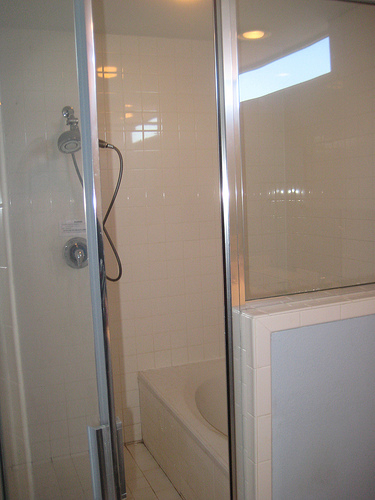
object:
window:
[236, 36, 332, 106]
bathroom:
[0, 0, 375, 500]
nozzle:
[61, 140, 79, 152]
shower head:
[57, 130, 114, 154]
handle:
[87, 416, 127, 500]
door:
[0, 0, 126, 500]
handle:
[99, 139, 114, 149]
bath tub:
[137, 357, 254, 499]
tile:
[255, 366, 272, 417]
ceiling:
[0, 1, 363, 38]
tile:
[155, 350, 172, 369]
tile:
[127, 187, 145, 207]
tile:
[143, 130, 161, 150]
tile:
[148, 224, 166, 243]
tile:
[182, 221, 199, 240]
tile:
[171, 330, 188, 349]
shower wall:
[3, 29, 243, 459]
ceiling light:
[242, 30, 265, 39]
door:
[86, 0, 233, 500]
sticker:
[58, 220, 86, 236]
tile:
[145, 187, 165, 208]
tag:
[59, 219, 88, 237]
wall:
[254, 298, 374, 500]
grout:
[127, 440, 144, 445]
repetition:
[123, 99, 197, 152]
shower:
[57, 105, 123, 283]